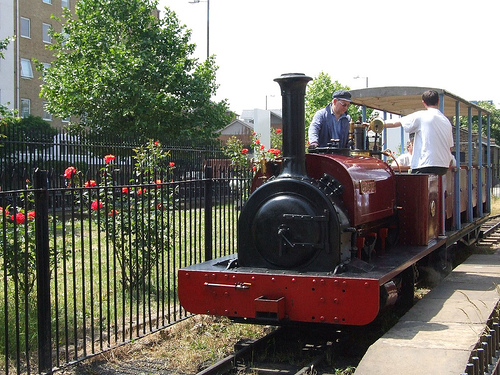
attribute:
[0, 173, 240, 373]
fence — black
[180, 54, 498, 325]
train — red, black, little, open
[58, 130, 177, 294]
bush — rose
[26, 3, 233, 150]
tree — green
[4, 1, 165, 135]
building — tall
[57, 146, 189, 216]
flowers — red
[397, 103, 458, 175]
shirt — white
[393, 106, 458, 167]
shirt — white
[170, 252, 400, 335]
bumper — red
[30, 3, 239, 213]
tree — big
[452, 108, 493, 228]
sticks — gray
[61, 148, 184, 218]
roses — red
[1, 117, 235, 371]
fence — black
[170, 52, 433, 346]
engine — black, red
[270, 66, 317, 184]
smoke stack — black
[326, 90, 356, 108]
cap — gray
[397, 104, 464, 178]
shirt — white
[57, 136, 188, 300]
rose bush — beautiful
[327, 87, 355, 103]
hat — blue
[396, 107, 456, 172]
shirt — white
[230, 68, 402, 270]
steam engine — replica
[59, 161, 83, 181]
rose — red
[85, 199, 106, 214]
rose — red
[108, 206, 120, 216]
rose — red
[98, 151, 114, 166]
rose — red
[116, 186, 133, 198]
rose — red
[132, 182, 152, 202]
rose — red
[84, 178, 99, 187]
rose — red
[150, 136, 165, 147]
rose — red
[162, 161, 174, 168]
rose — red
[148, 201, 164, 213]
rose — red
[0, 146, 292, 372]
fence — wrought, iron, black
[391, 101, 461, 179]
shirt — white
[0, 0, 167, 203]
building — tall, brick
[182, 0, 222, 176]
street light — tall